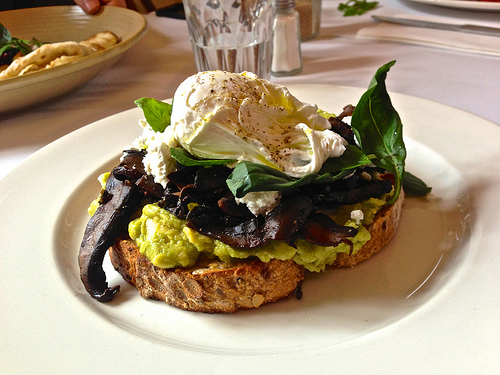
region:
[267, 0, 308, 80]
a salt shaker on the table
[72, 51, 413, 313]
an open faced sandwich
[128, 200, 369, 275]
guacamole on the sandwich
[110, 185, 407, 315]
a piece of wheat bread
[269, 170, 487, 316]
the shadow of the sandwich on the plate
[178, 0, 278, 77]
a glass on the table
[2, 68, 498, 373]
a white plate with a sandwich in it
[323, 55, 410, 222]
lettuce leaves on the sandwich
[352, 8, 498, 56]
napkins on the table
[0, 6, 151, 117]
a bowl of food on the table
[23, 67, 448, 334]
food on the plate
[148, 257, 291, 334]
bread under the food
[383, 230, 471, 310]
white plate under food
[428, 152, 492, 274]
shadow on the plate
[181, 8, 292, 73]
glass next to the plate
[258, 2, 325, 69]
salt in the photo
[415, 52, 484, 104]
table under the plate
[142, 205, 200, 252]
yellow food on bread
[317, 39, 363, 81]
shadow on the table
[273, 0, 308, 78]
a salt shaker on the table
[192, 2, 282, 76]
a glass on the table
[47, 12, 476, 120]
a white table cloth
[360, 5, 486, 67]
a napkin on the table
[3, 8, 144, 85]
a bowl of food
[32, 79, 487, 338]
a plate of food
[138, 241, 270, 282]
bread under the food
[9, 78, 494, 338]
a white plate on the table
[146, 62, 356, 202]
White sauce in the shot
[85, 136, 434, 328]
The buns are brown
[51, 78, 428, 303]
There is lettuce in the sandwich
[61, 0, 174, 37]
The hands are white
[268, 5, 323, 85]
Salt in the back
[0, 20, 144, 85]
Food in the plate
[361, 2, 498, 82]
Napkins on the table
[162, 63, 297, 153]
white egg on sandwich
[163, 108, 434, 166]
green leafy vegetable on sandwich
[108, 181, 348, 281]
green guacamole on sandwich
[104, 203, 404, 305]
brown whole grain bread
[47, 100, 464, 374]
sandwich on white plate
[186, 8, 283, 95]
clear glass of water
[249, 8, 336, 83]
small shaker of salt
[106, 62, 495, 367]
plate on white table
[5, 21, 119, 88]
small and white bowl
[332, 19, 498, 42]
silverware on white napkin